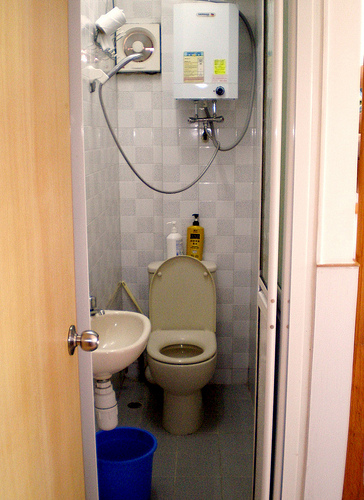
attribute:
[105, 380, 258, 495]
floor — grey, tile, tiled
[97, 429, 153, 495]
bucket — blue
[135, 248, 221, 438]
toilet — brown, white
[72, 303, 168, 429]
sink — white, small, empty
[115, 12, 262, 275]
wall — tile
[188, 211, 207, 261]
bottle — gold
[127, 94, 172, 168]
tile — grey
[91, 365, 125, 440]
pipe — white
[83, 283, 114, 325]
faucet — metal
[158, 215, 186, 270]
bottle — white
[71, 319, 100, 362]
knob — silver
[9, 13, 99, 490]
door — wooden, brown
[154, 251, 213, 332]
lid — up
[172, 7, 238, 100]
box — metal